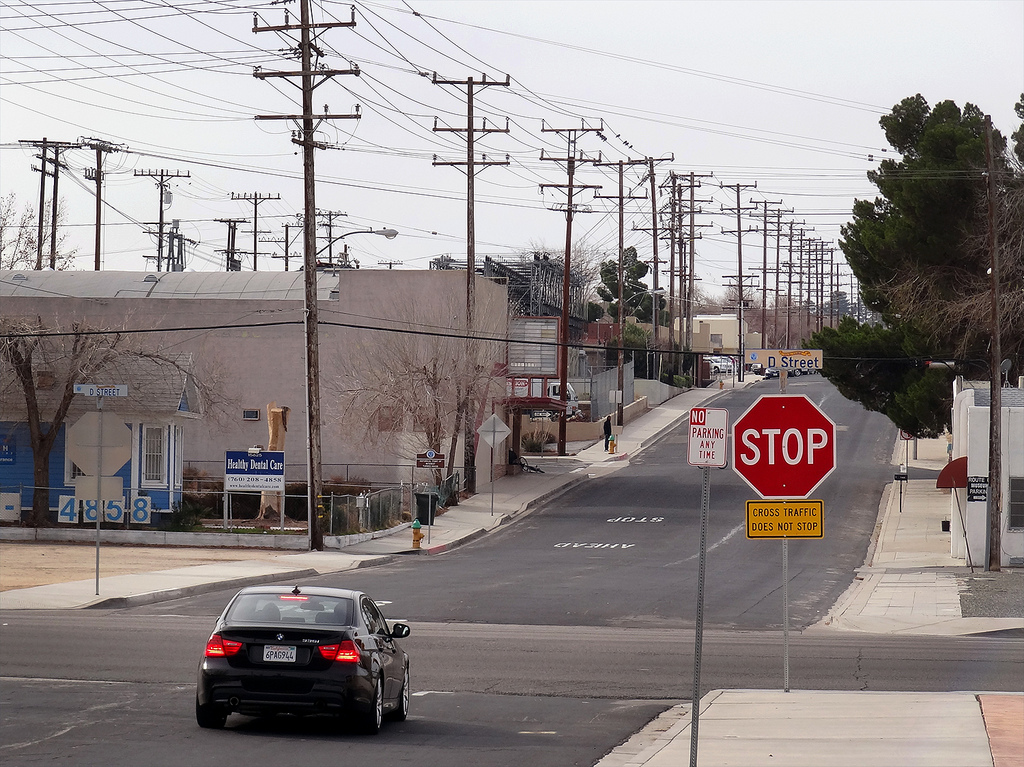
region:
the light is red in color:
[322, 638, 360, 670]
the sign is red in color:
[735, 388, 833, 500]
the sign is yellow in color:
[748, 503, 821, 536]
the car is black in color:
[212, 588, 440, 732]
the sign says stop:
[740, 401, 836, 497]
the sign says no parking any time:
[692, 407, 730, 468]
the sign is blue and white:
[221, 449, 286, 494]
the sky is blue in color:
[492, 206, 543, 246]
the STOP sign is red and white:
[732, 392, 837, 501]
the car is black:
[193, 584, 413, 733]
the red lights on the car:
[196, 582, 412, 729]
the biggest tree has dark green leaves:
[788, 91, 1022, 440]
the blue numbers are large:
[58, 495, 150, 530]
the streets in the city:
[2, 4, 1018, 764]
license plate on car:
[260, 647, 298, 664]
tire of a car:
[364, 678, 384, 726]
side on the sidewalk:
[684, 404, 726, 763]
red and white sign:
[729, 393, 832, 499]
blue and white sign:
[226, 445, 285, 490]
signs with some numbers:
[55, 492, 151, 522]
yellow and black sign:
[746, 501, 820, 537]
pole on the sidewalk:
[680, 723, 712, 756]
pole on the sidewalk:
[484, 480, 505, 512]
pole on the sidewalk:
[544, 429, 563, 452]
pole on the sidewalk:
[610, 411, 636, 434]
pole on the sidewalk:
[729, 350, 746, 385]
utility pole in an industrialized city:
[249, 0, 363, 544]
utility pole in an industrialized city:
[423, 65, 513, 490]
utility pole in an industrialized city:
[533, 112, 604, 461]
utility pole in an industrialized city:
[594, 153, 646, 426]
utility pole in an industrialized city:
[634, 150, 673, 379]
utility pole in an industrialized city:
[19, 133, 65, 269]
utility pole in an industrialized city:
[128, 159, 199, 270]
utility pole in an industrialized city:
[220, 184, 282, 270]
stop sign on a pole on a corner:
[727, 392, 838, 498]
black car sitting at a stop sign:
[193, 580, 419, 739]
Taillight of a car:
[324, 636, 366, 669]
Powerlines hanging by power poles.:
[5, 7, 1018, 722]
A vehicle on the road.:
[154, 542, 456, 748]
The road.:
[43, 349, 1021, 761]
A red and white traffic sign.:
[693, 396, 728, 476]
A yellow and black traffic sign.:
[738, 499, 827, 541]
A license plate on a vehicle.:
[258, 643, 303, 667]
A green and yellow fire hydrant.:
[599, 430, 625, 454]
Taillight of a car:
[199, 616, 244, 667]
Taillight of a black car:
[316, 635, 358, 671]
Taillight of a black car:
[201, 626, 250, 665]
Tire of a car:
[363, 670, 392, 737]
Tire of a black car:
[362, 661, 398, 745]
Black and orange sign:
[739, 495, 826, 544]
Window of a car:
[224, 588, 351, 621]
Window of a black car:
[230, 591, 349, 634]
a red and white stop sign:
[719, 380, 840, 694]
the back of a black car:
[196, 575, 415, 737]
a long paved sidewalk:
[807, 451, 970, 638]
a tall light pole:
[529, 117, 627, 441]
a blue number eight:
[125, 495, 152, 530]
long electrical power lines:
[431, 9, 887, 130]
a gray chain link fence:
[329, 476, 409, 528]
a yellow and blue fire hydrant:
[403, 515, 430, 550]